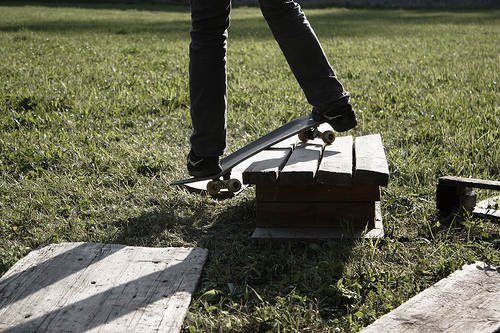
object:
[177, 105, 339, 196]
skateboard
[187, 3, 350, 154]
denim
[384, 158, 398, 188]
ground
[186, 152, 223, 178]
black shoes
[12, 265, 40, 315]
gray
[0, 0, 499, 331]
grass field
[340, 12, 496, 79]
grass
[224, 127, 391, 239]
base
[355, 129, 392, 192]
wood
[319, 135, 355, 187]
wood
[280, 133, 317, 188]
wood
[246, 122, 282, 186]
wood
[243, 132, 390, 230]
plank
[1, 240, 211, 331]
plywood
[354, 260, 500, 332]
plywood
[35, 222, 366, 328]
ground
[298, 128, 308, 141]
wheel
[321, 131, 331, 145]
wheel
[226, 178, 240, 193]
wheel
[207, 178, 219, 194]
wheel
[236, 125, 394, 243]
table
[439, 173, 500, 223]
wood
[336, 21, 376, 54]
grass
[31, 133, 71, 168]
grass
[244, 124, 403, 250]
funbox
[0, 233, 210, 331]
wooden plank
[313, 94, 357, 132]
foot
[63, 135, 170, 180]
green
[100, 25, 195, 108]
green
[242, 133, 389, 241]
timber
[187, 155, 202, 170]
logo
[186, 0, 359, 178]
boy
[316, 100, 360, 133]
shoes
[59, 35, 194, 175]
field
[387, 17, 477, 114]
field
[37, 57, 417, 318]
ground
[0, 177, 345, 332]
shadow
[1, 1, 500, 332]
yard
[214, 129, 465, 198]
step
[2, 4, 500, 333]
area